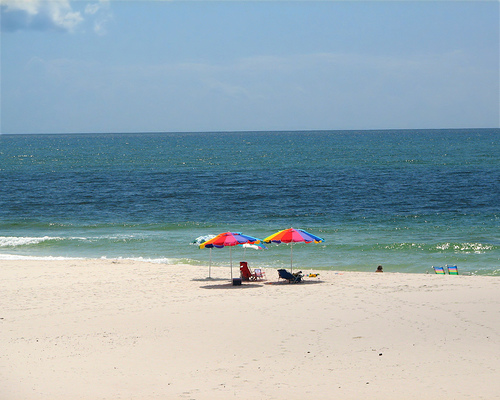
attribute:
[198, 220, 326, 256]
beach umbrellas — rainbow colored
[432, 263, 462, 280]
beach chairs — rainbow colored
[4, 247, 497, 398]
beach — sandy, white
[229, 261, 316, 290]
chairs — red, blue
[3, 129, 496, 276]
ocean — blue, green, choppy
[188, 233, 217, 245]
umbrella — green, white, blue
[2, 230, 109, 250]
wave — white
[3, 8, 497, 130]
sky — blue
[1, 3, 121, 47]
clouds — puffy, white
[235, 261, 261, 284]
chair — red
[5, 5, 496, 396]
picture — beach scene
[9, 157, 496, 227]
water section — blue